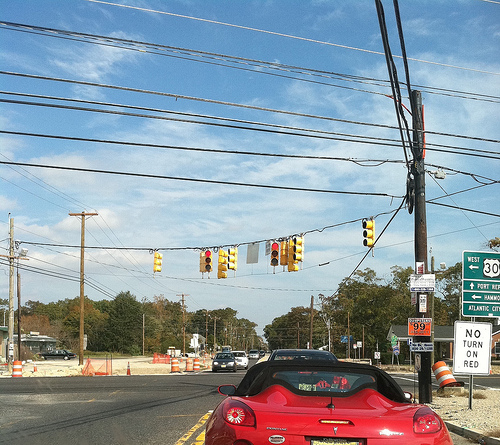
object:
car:
[200, 358, 455, 443]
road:
[22, 377, 197, 439]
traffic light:
[227, 247, 236, 270]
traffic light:
[361, 218, 376, 248]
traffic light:
[152, 250, 162, 276]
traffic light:
[291, 235, 305, 262]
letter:
[469, 337, 478, 349]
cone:
[192, 359, 202, 371]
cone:
[432, 359, 455, 389]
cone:
[11, 358, 23, 377]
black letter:
[465, 329, 472, 336]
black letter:
[473, 329, 481, 340]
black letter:
[474, 360, 479, 368]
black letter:
[464, 360, 468, 367]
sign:
[455, 321, 489, 373]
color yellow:
[152, 254, 164, 272]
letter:
[466, 340, 473, 346]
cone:
[170, 356, 181, 373]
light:
[268, 240, 282, 267]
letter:
[459, 358, 471, 370]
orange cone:
[123, 359, 133, 377]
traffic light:
[201, 248, 211, 275]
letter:
[474, 330, 484, 339]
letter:
[469, 347, 480, 359]